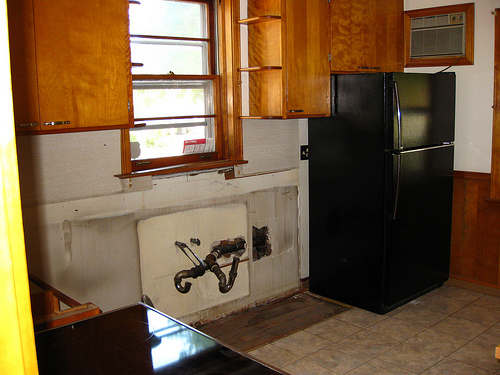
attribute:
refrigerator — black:
[306, 69, 459, 313]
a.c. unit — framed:
[408, 13, 468, 60]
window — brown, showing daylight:
[126, 2, 229, 173]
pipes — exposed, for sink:
[175, 240, 248, 294]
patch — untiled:
[189, 290, 352, 353]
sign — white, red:
[181, 140, 212, 153]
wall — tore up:
[17, 115, 306, 328]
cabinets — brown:
[239, 2, 407, 117]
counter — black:
[35, 299, 285, 374]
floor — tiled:
[218, 313, 500, 374]